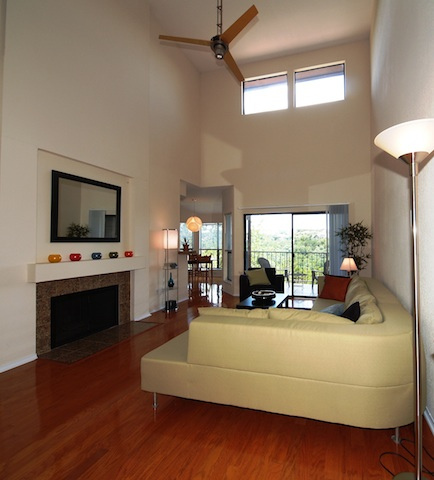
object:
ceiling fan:
[157, 4, 259, 82]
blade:
[222, 4, 259, 45]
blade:
[158, 34, 214, 46]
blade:
[223, 47, 245, 82]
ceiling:
[154, 1, 376, 74]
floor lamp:
[373, 118, 433, 479]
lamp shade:
[372, 116, 434, 163]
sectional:
[139, 275, 427, 446]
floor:
[1, 280, 434, 479]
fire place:
[35, 269, 131, 357]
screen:
[50, 284, 119, 345]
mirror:
[49, 168, 122, 243]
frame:
[50, 169, 122, 244]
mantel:
[26, 253, 143, 284]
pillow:
[318, 273, 351, 301]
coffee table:
[235, 289, 292, 310]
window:
[292, 59, 347, 110]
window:
[239, 71, 288, 115]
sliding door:
[243, 213, 328, 300]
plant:
[335, 219, 372, 277]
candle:
[48, 254, 61, 262]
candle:
[69, 253, 82, 263]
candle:
[91, 252, 102, 260]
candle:
[108, 250, 119, 259]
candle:
[123, 250, 134, 256]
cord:
[378, 435, 433, 478]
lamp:
[162, 228, 179, 250]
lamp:
[338, 256, 359, 272]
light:
[185, 215, 203, 233]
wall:
[0, 0, 149, 374]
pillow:
[244, 266, 271, 287]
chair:
[238, 265, 286, 303]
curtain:
[328, 203, 350, 277]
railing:
[249, 250, 327, 284]